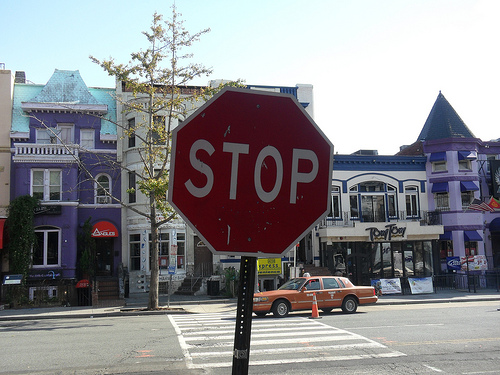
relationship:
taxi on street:
[251, 274, 380, 321] [0, 300, 499, 375]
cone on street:
[310, 291, 322, 320] [0, 300, 499, 375]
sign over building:
[253, 257, 283, 278] [216, 79, 298, 295]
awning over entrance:
[86, 220, 118, 238] [94, 235, 116, 277]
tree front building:
[21, 3, 249, 308] [116, 75, 211, 297]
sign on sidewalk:
[381, 276, 435, 296] [374, 290, 500, 303]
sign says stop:
[167, 88, 336, 260] [184, 136, 322, 208]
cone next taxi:
[310, 291, 322, 320] [251, 274, 380, 321]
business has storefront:
[321, 150, 442, 297] [328, 244, 436, 295]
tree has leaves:
[21, 3, 249, 308] [93, 11, 257, 219]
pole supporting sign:
[232, 257, 256, 374] [167, 88, 336, 260]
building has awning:
[415, 82, 492, 290] [461, 150, 477, 161]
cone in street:
[310, 291, 322, 320] [0, 300, 499, 375]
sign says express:
[253, 257, 283, 278] [261, 263, 282, 270]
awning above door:
[86, 220, 118, 238] [94, 235, 116, 277]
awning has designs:
[86, 220, 118, 238] [93, 229, 117, 237]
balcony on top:
[9, 140, 80, 164] [19, 112, 120, 164]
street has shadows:
[0, 300, 499, 375] [4, 315, 114, 336]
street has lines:
[0, 300, 499, 375] [165, 301, 446, 374]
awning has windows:
[430, 152, 446, 164] [434, 161, 447, 172]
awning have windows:
[461, 150, 477, 161] [462, 159, 471, 171]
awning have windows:
[467, 229, 478, 244] [466, 244, 477, 259]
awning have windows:
[433, 183, 450, 194] [436, 195, 448, 212]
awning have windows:
[462, 181, 477, 194] [462, 192, 472, 206]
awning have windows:
[439, 230, 452, 243] [440, 243, 453, 262]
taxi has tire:
[251, 274, 380, 321] [343, 296, 358, 314]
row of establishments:
[6, 65, 497, 307] [2, 65, 498, 311]